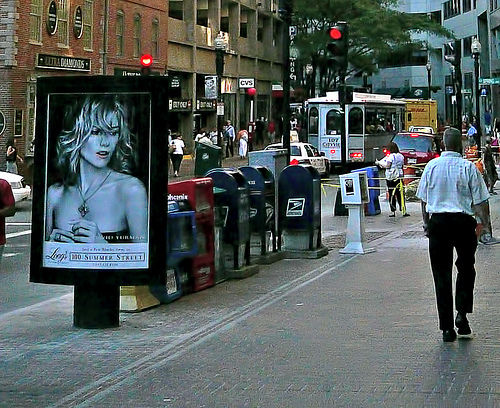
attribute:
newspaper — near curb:
[373, 153, 392, 167]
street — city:
[1, 274, 44, 302]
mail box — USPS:
[280, 162, 325, 261]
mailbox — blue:
[202, 165, 260, 279]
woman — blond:
[22, 67, 179, 287]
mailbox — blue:
[272, 166, 336, 263]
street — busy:
[5, 202, 77, 315]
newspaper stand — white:
[338, 170, 377, 253]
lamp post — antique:
[472, 35, 483, 152]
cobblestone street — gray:
[3, 187, 498, 404]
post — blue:
[239, 147, 292, 262]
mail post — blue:
[205, 163, 256, 272]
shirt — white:
[415, 148, 489, 218]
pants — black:
[427, 212, 480, 329]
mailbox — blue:
[275, 162, 327, 258]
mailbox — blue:
[239, 164, 283, 264]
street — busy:
[152, 100, 292, 174]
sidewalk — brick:
[215, 219, 435, 371]